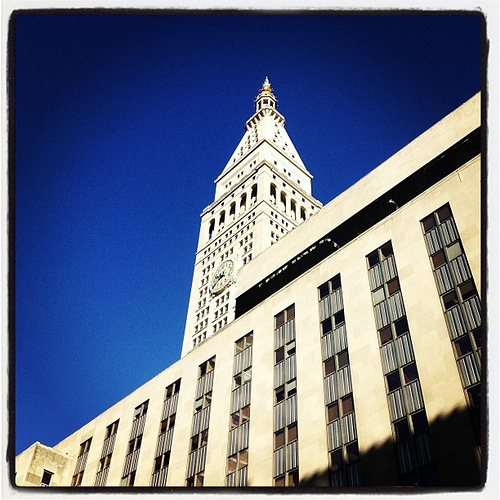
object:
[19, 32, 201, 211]
sky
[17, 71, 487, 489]
white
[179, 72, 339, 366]
tower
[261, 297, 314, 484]
line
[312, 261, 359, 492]
windows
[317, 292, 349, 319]
squares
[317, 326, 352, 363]
ridges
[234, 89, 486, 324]
platform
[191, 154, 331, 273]
arches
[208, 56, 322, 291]
narrow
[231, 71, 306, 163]
top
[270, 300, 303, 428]
window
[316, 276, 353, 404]
building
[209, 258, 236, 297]
clock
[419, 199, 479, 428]
row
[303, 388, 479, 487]
shadow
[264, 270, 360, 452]
eight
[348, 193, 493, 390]
set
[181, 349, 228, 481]
three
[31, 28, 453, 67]
blue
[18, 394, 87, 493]
part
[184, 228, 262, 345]
small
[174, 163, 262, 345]
windows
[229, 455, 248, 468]
light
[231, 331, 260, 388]
lit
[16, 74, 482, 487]
building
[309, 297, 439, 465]
wall